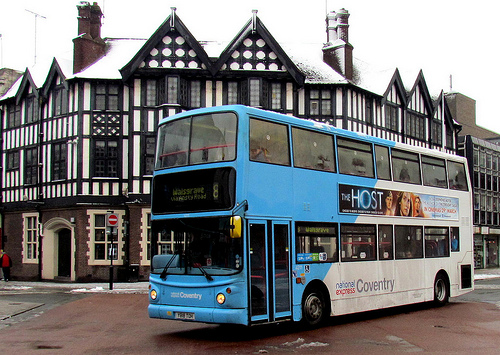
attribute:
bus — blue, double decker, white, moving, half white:
[154, 107, 474, 310]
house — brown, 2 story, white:
[7, 5, 494, 309]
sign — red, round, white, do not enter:
[101, 206, 127, 241]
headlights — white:
[150, 275, 249, 324]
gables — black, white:
[145, 25, 289, 87]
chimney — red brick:
[72, 1, 104, 73]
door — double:
[248, 216, 292, 315]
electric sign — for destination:
[159, 178, 224, 211]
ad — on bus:
[328, 168, 469, 234]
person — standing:
[3, 229, 32, 288]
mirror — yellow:
[230, 206, 248, 245]